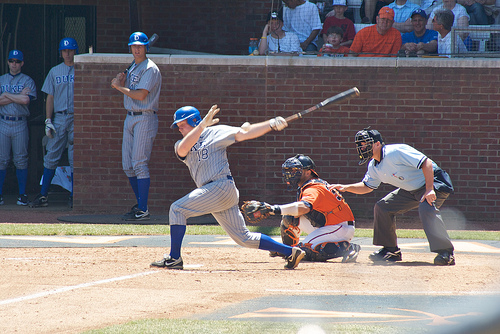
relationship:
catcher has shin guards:
[241, 151, 361, 266] [303, 239, 351, 263]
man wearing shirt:
[349, 2, 403, 56] [349, 23, 403, 56]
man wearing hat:
[349, 2, 403, 56] [375, 5, 397, 21]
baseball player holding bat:
[150, 102, 306, 269] [268, 86, 360, 129]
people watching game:
[245, 1, 499, 56] [8, 28, 499, 330]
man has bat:
[150, 102, 306, 269] [268, 86, 360, 129]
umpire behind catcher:
[332, 128, 457, 266] [241, 151, 361, 266]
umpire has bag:
[332, 128, 457, 266] [434, 167, 456, 194]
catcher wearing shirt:
[241, 151, 361, 266] [294, 176, 358, 226]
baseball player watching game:
[0, 47, 33, 208] [8, 28, 499, 330]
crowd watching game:
[245, 1, 499, 56] [8, 28, 499, 330]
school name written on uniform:
[55, 72, 78, 86] [45, 57, 78, 168]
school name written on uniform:
[1, 83, 27, 96] [1, 72, 35, 168]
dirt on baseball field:
[1, 244, 499, 334] [3, 203, 498, 333]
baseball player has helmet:
[150, 102, 306, 269] [168, 104, 204, 132]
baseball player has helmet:
[110, 29, 165, 222] [126, 30, 151, 50]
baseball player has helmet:
[36, 34, 78, 211] [55, 35, 81, 56]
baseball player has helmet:
[0, 47, 33, 208] [5, 46, 25, 64]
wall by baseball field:
[73, 56, 499, 225] [3, 203, 498, 333]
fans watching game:
[245, 1, 499, 56] [8, 28, 499, 330]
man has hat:
[349, 2, 403, 56] [375, 5, 397, 21]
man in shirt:
[399, 7, 439, 59] [401, 29, 439, 56]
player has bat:
[150, 102, 306, 269] [268, 86, 360, 129]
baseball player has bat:
[110, 29, 165, 222] [117, 29, 159, 88]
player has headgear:
[241, 151, 361, 266] [280, 157, 303, 189]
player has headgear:
[332, 128, 457, 266] [353, 126, 375, 167]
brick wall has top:
[73, 56, 499, 225] [73, 46, 499, 69]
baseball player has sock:
[150, 102, 306, 269] [257, 230, 293, 261]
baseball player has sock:
[150, 102, 306, 269] [170, 221, 187, 261]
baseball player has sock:
[110, 29, 165, 222] [127, 175, 154, 209]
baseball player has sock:
[36, 34, 78, 211] [40, 163, 59, 195]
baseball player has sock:
[0, 47, 33, 208] [13, 164, 32, 196]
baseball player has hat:
[150, 102, 306, 269] [168, 104, 204, 132]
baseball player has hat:
[110, 29, 165, 222] [126, 30, 151, 50]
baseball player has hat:
[36, 34, 78, 211] [60, 38, 78, 53]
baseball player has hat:
[0, 47, 33, 208] [5, 46, 25, 64]